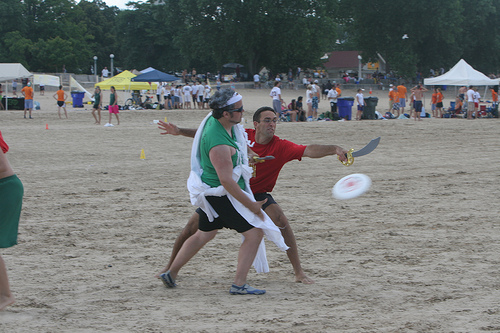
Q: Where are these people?
A: On the beach.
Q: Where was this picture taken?
A: The beach.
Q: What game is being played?
A: Frisbee.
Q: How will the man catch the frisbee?
A: With right hand.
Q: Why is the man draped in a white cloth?
A: It's a costume.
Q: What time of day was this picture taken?
A: Afternoon.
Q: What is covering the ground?
A: Sand.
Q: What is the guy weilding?
A: A sword.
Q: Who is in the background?
A: The people.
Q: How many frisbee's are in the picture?
A: One.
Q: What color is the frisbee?
A: White.